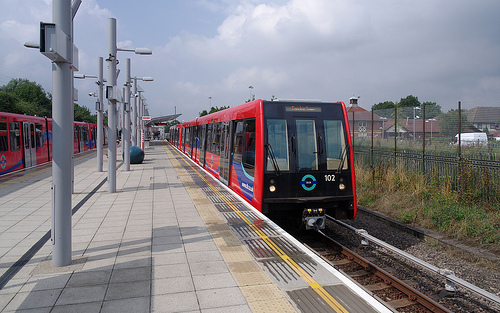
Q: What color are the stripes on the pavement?
A: Yellow.